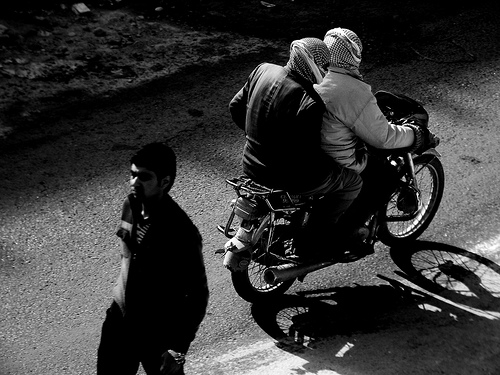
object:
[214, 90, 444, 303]
motorcycle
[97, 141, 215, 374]
man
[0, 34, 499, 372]
road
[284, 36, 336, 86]
headcovering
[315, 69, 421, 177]
driver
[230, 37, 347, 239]
person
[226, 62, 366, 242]
clothes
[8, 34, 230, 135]
area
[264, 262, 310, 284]
pipe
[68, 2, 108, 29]
debris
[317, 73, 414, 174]
jacket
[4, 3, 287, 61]
dirt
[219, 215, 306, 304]
wheel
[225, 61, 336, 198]
jacket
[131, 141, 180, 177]
hair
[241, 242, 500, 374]
shadow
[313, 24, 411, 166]
person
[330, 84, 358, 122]
white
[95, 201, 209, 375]
suit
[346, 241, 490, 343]
line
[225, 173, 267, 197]
rack